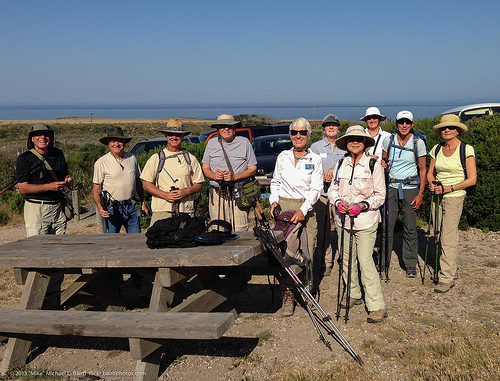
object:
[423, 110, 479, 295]
people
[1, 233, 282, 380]
table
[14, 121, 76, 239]
man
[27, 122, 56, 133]
hat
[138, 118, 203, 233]
man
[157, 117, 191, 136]
hat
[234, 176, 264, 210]
bag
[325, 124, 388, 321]
woman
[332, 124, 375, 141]
hat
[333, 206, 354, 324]
poles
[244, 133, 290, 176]
vehicles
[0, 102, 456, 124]
water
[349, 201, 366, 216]
gloves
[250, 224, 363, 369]
equipment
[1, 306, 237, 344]
seat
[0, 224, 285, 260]
top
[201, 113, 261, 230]
man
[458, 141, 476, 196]
backpack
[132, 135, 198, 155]
car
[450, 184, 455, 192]
watch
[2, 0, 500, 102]
sky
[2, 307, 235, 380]
bench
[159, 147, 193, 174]
backback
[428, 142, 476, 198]
shirt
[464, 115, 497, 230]
bush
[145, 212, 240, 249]
bag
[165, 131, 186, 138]
glasses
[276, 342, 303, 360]
gravel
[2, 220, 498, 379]
ground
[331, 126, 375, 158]
head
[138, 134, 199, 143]
roof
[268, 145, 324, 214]
shirt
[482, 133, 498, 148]
leaves